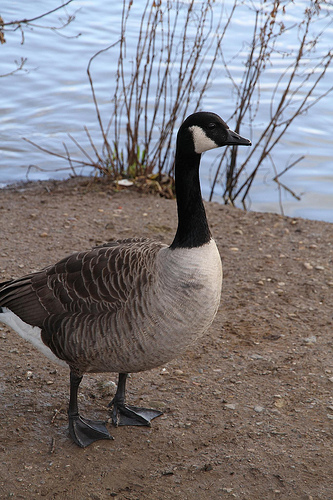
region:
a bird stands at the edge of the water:
[0, 102, 316, 457]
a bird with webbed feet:
[4, 103, 268, 445]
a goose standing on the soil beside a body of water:
[18, 104, 271, 446]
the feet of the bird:
[39, 382, 188, 465]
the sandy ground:
[231, 239, 323, 497]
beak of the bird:
[224, 124, 255, 154]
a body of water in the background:
[8, 6, 312, 126]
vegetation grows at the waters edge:
[115, 0, 181, 202]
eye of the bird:
[203, 120, 216, 132]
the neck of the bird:
[170, 152, 211, 240]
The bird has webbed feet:
[55, 386, 194, 479]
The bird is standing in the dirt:
[10, 359, 302, 498]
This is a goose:
[3, 81, 239, 334]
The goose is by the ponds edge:
[10, 74, 294, 304]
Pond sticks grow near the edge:
[40, 15, 310, 176]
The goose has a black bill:
[210, 104, 258, 163]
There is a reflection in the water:
[268, 138, 331, 234]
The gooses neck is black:
[146, 149, 235, 267]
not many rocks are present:
[4, 349, 320, 469]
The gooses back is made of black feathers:
[8, 236, 158, 336]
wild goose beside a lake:
[2, 102, 260, 461]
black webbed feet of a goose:
[57, 365, 168, 462]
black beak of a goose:
[223, 126, 257, 151]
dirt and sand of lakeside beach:
[16, 185, 124, 240]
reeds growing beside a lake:
[75, 62, 171, 205]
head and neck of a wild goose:
[159, 105, 256, 244]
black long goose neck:
[164, 149, 208, 234]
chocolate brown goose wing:
[7, 240, 154, 316]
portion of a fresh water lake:
[4, 4, 117, 203]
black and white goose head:
[170, 103, 255, 160]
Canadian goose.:
[126, 78, 267, 233]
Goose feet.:
[41, 364, 172, 463]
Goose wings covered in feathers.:
[26, 264, 167, 363]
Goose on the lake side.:
[73, 81, 288, 359]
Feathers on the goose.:
[22, 220, 220, 413]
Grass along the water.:
[73, 46, 307, 213]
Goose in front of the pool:
[14, 67, 308, 314]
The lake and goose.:
[221, 169, 327, 250]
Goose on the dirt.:
[43, 399, 232, 497]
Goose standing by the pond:
[51, 98, 301, 384]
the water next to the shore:
[1, 1, 332, 219]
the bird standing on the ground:
[4, 109, 260, 446]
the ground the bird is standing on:
[3, 187, 331, 497]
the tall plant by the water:
[79, 1, 332, 217]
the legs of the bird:
[57, 370, 165, 446]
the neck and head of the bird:
[166, 109, 252, 257]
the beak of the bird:
[226, 124, 254, 149]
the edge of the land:
[7, 166, 331, 249]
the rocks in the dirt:
[215, 388, 290, 443]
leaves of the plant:
[131, 173, 172, 196]